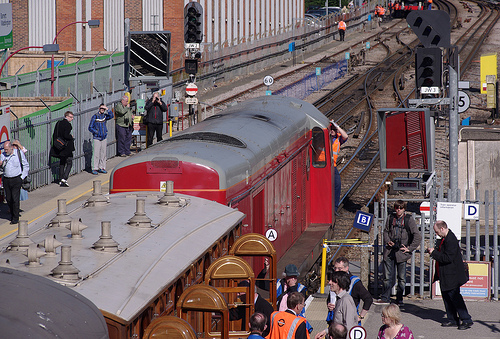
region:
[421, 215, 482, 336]
The man is standing.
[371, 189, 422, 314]
The man is standing.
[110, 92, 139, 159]
The man is standing.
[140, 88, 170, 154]
The man is standing.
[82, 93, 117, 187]
The man is standing.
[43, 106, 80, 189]
The man is standing.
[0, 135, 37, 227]
The man is standing.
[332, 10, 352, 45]
The man is standing.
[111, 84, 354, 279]
The man is on the train.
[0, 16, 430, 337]
The train is on the tracks.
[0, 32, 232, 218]
People waiting for the train on the platform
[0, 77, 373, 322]
A train arrived at the station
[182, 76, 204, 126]
White and red round sign on the pole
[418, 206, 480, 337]
A man in black suit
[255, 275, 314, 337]
A man wearing an orange safety vest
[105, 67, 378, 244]
Red engine of the train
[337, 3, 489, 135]
Railway tracks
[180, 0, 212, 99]
Signal for trains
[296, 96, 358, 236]
Engine driver wearing an orange safety vest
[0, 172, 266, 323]
Passenger car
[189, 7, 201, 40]
traffic light near the train.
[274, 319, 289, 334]
orange vest on man.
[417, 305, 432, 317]
shadow on the platform.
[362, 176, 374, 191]
wooden slats between tracks.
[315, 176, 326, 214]
door of the train.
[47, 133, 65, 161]
bag over man's shoulder.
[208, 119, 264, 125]
top of the train.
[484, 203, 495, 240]
metal fence on platform.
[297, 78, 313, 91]
blue fencing near the tracks.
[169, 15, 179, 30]
bricks on the building.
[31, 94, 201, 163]
people at the platform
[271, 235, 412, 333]
people at the platform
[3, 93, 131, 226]
people at the platform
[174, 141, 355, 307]
the train car is red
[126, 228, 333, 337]
train's doors are brown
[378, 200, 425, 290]
man carrying a camera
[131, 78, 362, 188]
train's roof is gray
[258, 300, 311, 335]
the vest is neon orange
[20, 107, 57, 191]
the fence is gray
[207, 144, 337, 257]
the train is red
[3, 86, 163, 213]
people standing on platform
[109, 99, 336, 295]
red and gray train car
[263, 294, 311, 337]
man in orange vest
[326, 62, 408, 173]
intersecting train tracks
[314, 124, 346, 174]
man in orange vest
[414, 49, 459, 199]
traffic lights on grey pole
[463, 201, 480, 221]
black letter on white square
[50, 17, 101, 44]
light on curved red pole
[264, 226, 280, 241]
letter on round sign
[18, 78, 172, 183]
poles on metal fence